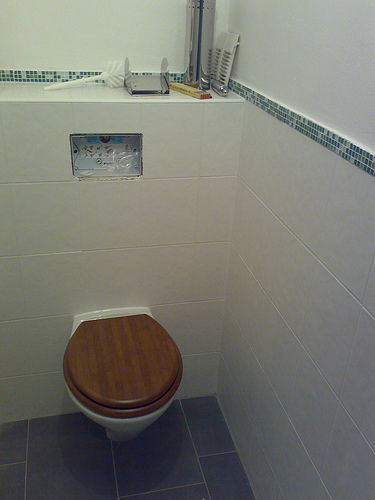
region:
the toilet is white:
[67, 312, 181, 440]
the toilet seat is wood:
[64, 313, 189, 411]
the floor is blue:
[4, 394, 257, 498]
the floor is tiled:
[0, 395, 256, 498]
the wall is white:
[0, 0, 374, 498]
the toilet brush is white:
[42, 62, 132, 95]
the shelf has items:
[43, 0, 244, 100]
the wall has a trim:
[1, 68, 374, 170]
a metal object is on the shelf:
[122, 60, 170, 99]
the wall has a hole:
[68, 132, 146, 182]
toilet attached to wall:
[39, 287, 189, 446]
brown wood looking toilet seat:
[58, 309, 185, 433]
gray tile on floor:
[17, 427, 207, 498]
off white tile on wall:
[245, 326, 351, 492]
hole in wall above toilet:
[56, 127, 194, 447]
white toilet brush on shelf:
[43, 56, 131, 97]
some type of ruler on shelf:
[165, 73, 215, 102]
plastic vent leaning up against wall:
[204, 25, 240, 94]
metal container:
[177, 0, 224, 90]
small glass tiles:
[283, 108, 357, 155]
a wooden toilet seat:
[62, 310, 185, 419]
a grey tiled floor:
[1, 393, 255, 498]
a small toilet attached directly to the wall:
[58, 303, 187, 444]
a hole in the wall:
[65, 129, 151, 179]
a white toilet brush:
[40, 58, 126, 93]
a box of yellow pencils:
[167, 79, 212, 99]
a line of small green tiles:
[226, 76, 373, 173]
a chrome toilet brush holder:
[185, 1, 216, 90]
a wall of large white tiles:
[1, 100, 245, 420]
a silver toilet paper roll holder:
[209, 77, 232, 98]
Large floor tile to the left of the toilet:
[37, 424, 87, 489]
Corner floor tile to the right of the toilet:
[193, 404, 218, 437]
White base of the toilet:
[111, 426, 130, 438]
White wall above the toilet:
[49, 208, 173, 296]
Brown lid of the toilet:
[97, 331, 145, 383]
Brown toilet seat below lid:
[109, 407, 150, 415]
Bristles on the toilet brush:
[100, 58, 127, 90]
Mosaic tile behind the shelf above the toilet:
[5, 65, 43, 83]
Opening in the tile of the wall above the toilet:
[58, 126, 156, 187]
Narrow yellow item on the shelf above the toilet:
[167, 80, 211, 102]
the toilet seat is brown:
[63, 315, 182, 410]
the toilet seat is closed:
[61, 316, 205, 436]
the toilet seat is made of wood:
[63, 303, 199, 424]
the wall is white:
[30, 212, 210, 288]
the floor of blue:
[36, 442, 109, 494]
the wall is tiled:
[37, 220, 142, 295]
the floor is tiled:
[19, 431, 120, 494]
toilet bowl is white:
[57, 310, 184, 456]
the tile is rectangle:
[180, 420, 250, 485]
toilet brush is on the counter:
[33, 52, 132, 93]